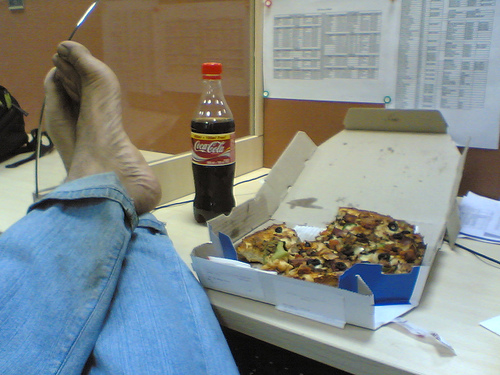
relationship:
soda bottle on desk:
[190, 61, 238, 228] [0, 133, 498, 374]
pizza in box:
[238, 206, 426, 287] [190, 107, 470, 330]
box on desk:
[190, 107, 470, 330] [0, 133, 498, 374]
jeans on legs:
[0, 172, 241, 375] [1, 39, 243, 372]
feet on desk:
[42, 39, 165, 215] [0, 133, 498, 374]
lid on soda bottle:
[199, 60, 222, 77] [190, 61, 238, 228]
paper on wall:
[263, 0, 388, 103] [262, 1, 498, 198]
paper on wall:
[388, 0, 499, 152] [262, 1, 498, 198]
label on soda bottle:
[190, 131, 237, 167] [190, 61, 238, 228]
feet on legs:
[42, 39, 165, 215] [1, 39, 243, 372]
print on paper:
[272, 7, 381, 83] [263, 0, 388, 103]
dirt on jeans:
[83, 191, 134, 294] [0, 172, 241, 375]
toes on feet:
[52, 38, 86, 103] [42, 39, 165, 215]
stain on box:
[284, 195, 324, 213] [190, 107, 470, 330]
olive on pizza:
[334, 261, 347, 271] [238, 206, 426, 287]